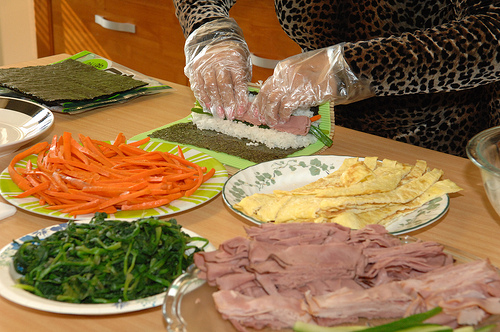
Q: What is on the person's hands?
A: Gloves.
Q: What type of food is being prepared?
A: Sushi roll.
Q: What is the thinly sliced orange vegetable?
A: Carrots.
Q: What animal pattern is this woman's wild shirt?
A: Cheetah.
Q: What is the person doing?
A: Cooking.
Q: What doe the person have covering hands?
A: Plastic gloves.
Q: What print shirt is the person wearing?
A: Leopard print.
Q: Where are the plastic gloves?
A: Covering persons hands.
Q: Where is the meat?
A: On a clear plate in the foreground.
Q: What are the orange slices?
A: Carrots.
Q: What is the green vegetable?
A: Seaweed.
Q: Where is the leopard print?
A: On the person's shirt.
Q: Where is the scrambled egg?
A: On plate with green ivy.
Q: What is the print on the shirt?
A: Leopard.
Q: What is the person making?
A: Sushi rolls.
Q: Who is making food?
A: A lady.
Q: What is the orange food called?
A: Carrots.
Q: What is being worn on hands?
A: Clear plastic gloves.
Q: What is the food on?
A: Plates.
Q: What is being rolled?
A: Sushi.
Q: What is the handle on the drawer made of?
A: Metal.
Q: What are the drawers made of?
A: Wood.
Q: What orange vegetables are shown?
A: Carrots.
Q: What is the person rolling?
A: Sushi roll.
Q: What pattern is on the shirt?
A: Leopard.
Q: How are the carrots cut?
A: Shredded.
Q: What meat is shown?
A: Ham.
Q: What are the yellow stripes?
A: Omelets.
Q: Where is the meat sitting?
A: Platter.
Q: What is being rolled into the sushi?
A: Seaweed.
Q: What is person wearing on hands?
A: Gloves.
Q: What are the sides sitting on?
A: Plates.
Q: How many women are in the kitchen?
A: One.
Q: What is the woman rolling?
A: Sushi.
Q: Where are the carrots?
A: On a plate.